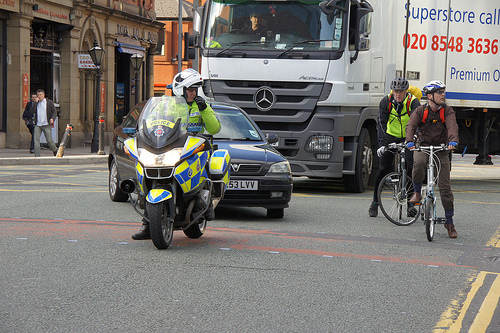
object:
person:
[126, 67, 221, 241]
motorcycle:
[120, 98, 231, 251]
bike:
[404, 142, 461, 242]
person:
[367, 77, 426, 220]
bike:
[376, 141, 422, 228]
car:
[111, 97, 293, 222]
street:
[0, 159, 500, 331]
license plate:
[221, 180, 259, 191]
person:
[32, 90, 59, 158]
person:
[21, 93, 45, 154]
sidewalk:
[3, 144, 121, 166]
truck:
[176, 1, 499, 195]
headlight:
[304, 134, 334, 161]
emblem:
[252, 86, 278, 113]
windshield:
[211, 108, 266, 140]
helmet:
[422, 81, 447, 96]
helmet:
[389, 77, 410, 91]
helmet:
[170, 68, 204, 99]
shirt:
[35, 98, 52, 127]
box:
[391, 0, 499, 112]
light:
[88, 41, 107, 67]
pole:
[89, 41, 110, 153]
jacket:
[376, 92, 422, 150]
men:
[404, 82, 464, 245]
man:
[240, 11, 268, 38]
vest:
[384, 93, 416, 139]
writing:
[420, 6, 429, 24]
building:
[151, 1, 231, 102]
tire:
[108, 156, 131, 201]